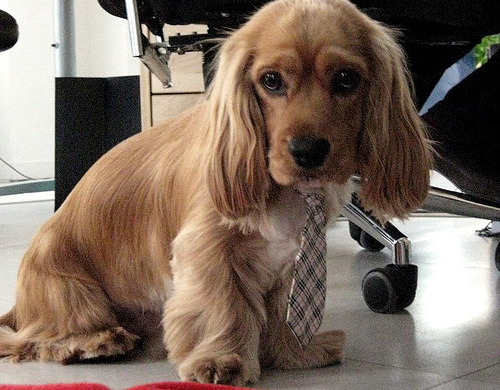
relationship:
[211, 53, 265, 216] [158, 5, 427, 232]
hair on dogs ears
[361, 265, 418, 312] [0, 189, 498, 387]
wheel on floor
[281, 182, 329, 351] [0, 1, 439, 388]
tie on dog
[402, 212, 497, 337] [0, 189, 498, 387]
sunlight reflection on floor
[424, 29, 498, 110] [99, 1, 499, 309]
gap in chair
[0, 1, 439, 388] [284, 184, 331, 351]
dog wearing tie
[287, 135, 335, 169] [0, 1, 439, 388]
nose on dog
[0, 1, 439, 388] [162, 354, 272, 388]
dog has paw